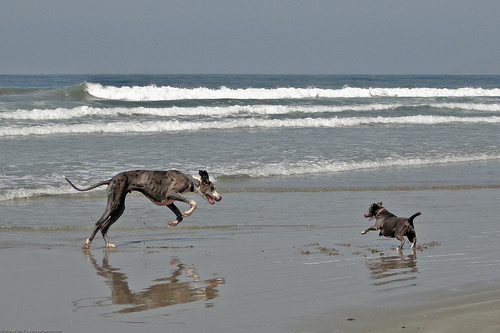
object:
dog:
[63, 170, 223, 249]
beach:
[0, 160, 498, 332]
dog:
[361, 201, 421, 248]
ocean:
[2, 74, 496, 197]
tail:
[409, 212, 421, 221]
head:
[198, 170, 222, 205]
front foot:
[168, 218, 183, 227]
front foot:
[181, 202, 197, 216]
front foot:
[361, 230, 369, 234]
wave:
[84, 80, 500, 102]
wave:
[3, 103, 500, 116]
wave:
[0, 115, 500, 138]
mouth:
[206, 194, 220, 205]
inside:
[208, 196, 214, 203]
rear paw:
[82, 245, 89, 249]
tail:
[63, 175, 109, 191]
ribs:
[138, 172, 166, 194]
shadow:
[72, 249, 225, 316]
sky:
[0, 3, 498, 79]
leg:
[83, 185, 127, 249]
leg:
[100, 194, 126, 248]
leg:
[166, 202, 183, 227]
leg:
[166, 179, 197, 217]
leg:
[362, 222, 381, 234]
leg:
[394, 226, 407, 249]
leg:
[407, 233, 417, 248]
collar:
[376, 208, 386, 218]